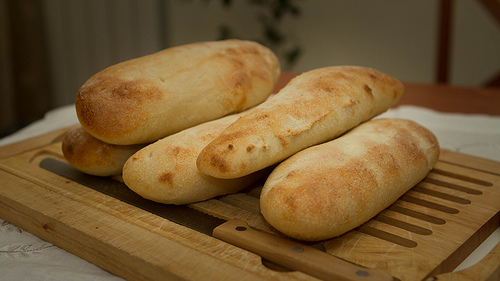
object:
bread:
[74, 37, 282, 145]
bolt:
[235, 225, 248, 232]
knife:
[38, 156, 393, 280]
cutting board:
[0, 121, 500, 280]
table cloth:
[1, 92, 499, 280]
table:
[0, 68, 499, 279]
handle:
[428, 236, 499, 279]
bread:
[259, 114, 441, 242]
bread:
[195, 63, 405, 179]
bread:
[122, 98, 285, 206]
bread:
[62, 124, 150, 177]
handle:
[212, 216, 394, 280]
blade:
[37, 156, 227, 237]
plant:
[211, 2, 304, 73]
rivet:
[353, 268, 371, 278]